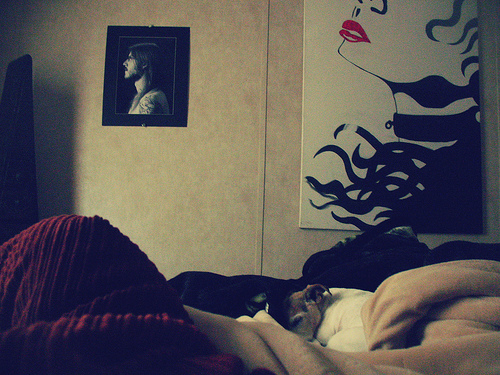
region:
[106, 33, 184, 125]
Picture hanging on wall.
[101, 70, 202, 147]
Black frame around picture.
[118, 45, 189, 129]
Picture of man on wall.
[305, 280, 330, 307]
Dog has brown ear.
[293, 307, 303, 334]
Dog has eye closed.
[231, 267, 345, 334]
Dog is laying on bed.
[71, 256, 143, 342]
Red blanket on bed.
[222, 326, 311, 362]
Tan blanket on bed.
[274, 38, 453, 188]
Large picture hanging on wall.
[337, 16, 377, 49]
Red lips on picture on wall.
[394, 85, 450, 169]
this is a painting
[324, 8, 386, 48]
this is a mouth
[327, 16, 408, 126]
the mouth is red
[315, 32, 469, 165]
this is a choker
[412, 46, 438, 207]
the choker is black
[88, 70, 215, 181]
this is a photo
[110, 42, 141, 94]
the photo is black and white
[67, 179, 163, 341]
this is a blanket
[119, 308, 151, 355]
the blanket is red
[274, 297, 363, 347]
this is a dog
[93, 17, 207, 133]
The picture hanging on the wall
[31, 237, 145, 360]
The blanket on the bed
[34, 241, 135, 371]
he blanket is the color burgundy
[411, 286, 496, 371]
The blanket is the color beige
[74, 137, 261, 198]
The wall is the color beige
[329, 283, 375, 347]
The pillow on the bed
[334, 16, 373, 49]
The lips of the woman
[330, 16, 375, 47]
The lips are painted red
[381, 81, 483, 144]
The neck of the woman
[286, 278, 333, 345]
The head of a dog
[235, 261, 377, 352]
a dog sleeping in a bed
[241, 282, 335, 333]
the head of a sleeping dog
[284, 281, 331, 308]
the ear of a sleeping dog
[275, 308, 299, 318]
the eye of a sleeping dog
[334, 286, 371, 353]
the body of a sleeping dog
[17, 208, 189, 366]
a large red fluffy blanket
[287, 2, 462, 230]
a black and white painting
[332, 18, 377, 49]
the red lips of a woman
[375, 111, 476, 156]
the choker of a woman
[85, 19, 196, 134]
a picture of a man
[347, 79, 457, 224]
this is a painting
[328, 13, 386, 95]
this is a mouth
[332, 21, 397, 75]
this is some lipstick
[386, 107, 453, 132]
this is a choker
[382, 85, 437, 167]
the choker is black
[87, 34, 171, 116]
the photo is black and white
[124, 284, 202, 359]
this is a blanket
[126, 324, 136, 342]
the blanket is red